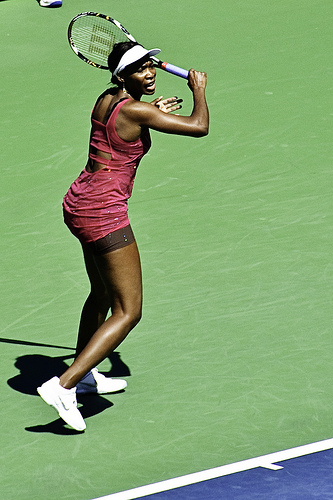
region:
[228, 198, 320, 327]
this is the ground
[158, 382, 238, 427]
the ground is green in color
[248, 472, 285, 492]
the ground is blue in color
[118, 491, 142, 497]
this is a marking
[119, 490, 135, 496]
the marking is white in color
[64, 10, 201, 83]
this is a racket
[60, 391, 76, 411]
the shoe is white in color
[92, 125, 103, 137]
the cloth is purple in color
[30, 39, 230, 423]
this is a woman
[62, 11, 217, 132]
the woman is holding the racket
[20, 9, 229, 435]
A woman playing tennis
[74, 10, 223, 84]
A woman holding tennis rocket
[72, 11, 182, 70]
Multi colored tennis rocket with white color net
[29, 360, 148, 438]
Pair of white color shoes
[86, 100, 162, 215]
A woman wearing pink color top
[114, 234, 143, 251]
A woman wearing brown color bottom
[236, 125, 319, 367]
Tennis court with green color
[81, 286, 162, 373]
Legs of the woman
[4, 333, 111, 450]
Shadow of the woman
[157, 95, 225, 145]
Hands of the woman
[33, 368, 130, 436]
tennis shoes on turf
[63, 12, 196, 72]
tennis racket in game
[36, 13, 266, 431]
women playing tennis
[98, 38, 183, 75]
head visor she is wearing.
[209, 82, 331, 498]
turf on tennis court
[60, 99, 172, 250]
red 1 piece jumper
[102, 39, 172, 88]
women playing tennis wearing visor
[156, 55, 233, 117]
right hand holding tennis racket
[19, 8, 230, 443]
healthy women playing tennis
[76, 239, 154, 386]
strong legs of tennis player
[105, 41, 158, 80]
THE WOMAN IS WEARING A VISOR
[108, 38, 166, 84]
THE VISOR THE WOMAN IS WEARING IS WHITE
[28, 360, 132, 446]
THE WOMAN IS WEARING WHITE SHOES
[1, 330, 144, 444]
THE WOMAN IS CASTING A SHADOW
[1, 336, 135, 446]
THE SHADOW IS ON THE GROUND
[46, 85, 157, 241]
THE WOMAN IS WEARING A TANK TOP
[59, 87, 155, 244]
THE WOMAN'S TANK TOP IS PINK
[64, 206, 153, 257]
THE WOMAN IS WEARING TIGHT DARK BROWN SHORTS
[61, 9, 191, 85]
THE WOMAN IS HOLDING A RACKET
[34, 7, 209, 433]
THE WOMAN IS PLAYING TENNIS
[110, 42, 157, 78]
the woman is wearing a cap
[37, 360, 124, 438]
the woman is wearing sneakers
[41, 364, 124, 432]
the sneakers are white in color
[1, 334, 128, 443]
a shadow is on the ground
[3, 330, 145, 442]
the woman is casting a shadow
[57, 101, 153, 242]
the woman is wearing a sleeveless outfit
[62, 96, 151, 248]
the outfit is red in color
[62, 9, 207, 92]
the woman is holding a racket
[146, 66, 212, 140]
the woman has her arm bent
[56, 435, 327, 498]
a white line is on the ground